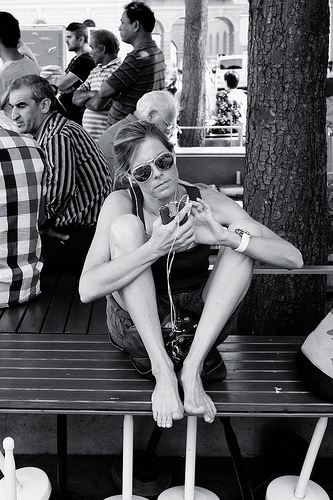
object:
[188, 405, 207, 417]
toe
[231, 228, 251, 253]
watch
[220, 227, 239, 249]
wrist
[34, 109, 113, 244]
shirt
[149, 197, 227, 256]
hands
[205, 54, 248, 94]
stand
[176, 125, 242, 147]
base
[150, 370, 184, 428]
foot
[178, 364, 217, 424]
foot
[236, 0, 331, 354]
tree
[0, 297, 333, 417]
surface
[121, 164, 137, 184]
ear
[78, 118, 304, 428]
woman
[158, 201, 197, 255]
cell phone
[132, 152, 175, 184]
sunglasses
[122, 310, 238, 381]
purse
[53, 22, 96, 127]
men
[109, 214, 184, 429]
legs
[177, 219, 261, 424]
legs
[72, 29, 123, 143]
men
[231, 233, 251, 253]
band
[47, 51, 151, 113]
arms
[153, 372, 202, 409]
veins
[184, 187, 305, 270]
arm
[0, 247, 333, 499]
bench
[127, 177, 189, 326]
earphones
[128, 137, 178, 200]
face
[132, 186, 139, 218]
cord